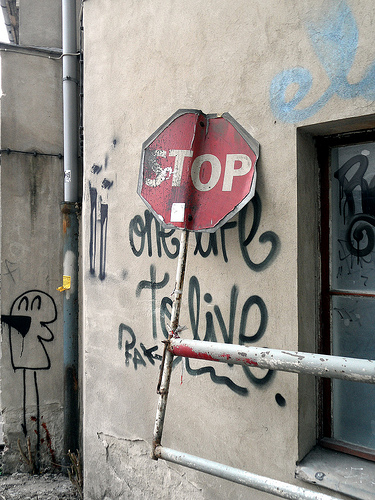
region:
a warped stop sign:
[140, 105, 262, 240]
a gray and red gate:
[132, 324, 374, 498]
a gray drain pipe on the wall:
[57, 35, 87, 482]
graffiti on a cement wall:
[86, 154, 293, 426]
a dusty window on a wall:
[294, 119, 372, 465]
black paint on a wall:
[4, 274, 63, 447]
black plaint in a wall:
[86, 161, 292, 416]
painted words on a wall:
[103, 195, 288, 408]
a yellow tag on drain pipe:
[54, 274, 76, 294]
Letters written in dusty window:
[333, 154, 374, 269]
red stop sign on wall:
[129, 113, 247, 233]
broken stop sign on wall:
[118, 103, 267, 233]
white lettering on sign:
[131, 141, 260, 203]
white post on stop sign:
[137, 231, 194, 456]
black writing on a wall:
[107, 210, 270, 375]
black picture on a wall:
[0, 286, 63, 372]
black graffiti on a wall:
[7, 274, 56, 374]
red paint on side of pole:
[176, 340, 230, 365]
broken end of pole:
[133, 316, 183, 425]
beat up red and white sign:
[160, 117, 262, 238]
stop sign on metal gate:
[148, 329, 229, 369]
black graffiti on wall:
[118, 325, 156, 382]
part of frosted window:
[291, 401, 374, 490]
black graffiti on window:
[329, 152, 371, 251]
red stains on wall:
[24, 433, 70, 472]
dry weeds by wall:
[62, 453, 81, 484]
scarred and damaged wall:
[99, 436, 148, 489]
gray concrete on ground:
[15, 477, 33, 488]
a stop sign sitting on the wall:
[135, 108, 261, 231]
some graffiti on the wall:
[6, 291, 62, 441]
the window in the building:
[321, 146, 374, 442]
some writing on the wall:
[117, 201, 282, 385]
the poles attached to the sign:
[145, 234, 373, 499]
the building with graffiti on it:
[80, 5, 371, 494]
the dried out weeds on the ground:
[18, 432, 86, 492]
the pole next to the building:
[54, 0, 88, 486]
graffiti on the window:
[328, 152, 369, 244]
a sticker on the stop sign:
[168, 203, 188, 226]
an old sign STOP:
[132, 103, 265, 241]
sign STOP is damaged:
[130, 100, 272, 239]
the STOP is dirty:
[131, 102, 263, 246]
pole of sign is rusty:
[151, 232, 186, 453]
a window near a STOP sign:
[137, 88, 373, 476]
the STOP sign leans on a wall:
[109, 85, 296, 278]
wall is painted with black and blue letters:
[75, 11, 369, 427]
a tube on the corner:
[49, 15, 98, 480]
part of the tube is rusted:
[49, 186, 89, 291]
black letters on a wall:
[90, 176, 301, 403]